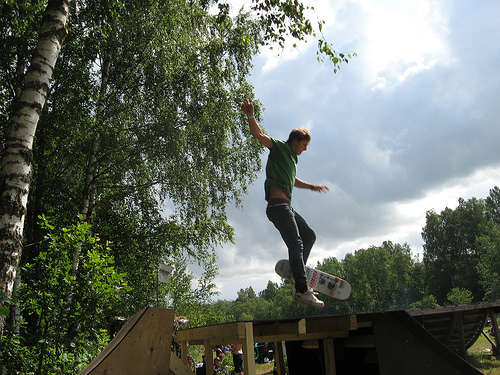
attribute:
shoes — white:
[289, 288, 328, 306]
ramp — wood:
[129, 290, 243, 353]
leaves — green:
[104, 137, 164, 221]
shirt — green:
[254, 134, 306, 191]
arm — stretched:
[224, 84, 275, 149]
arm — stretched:
[284, 168, 332, 203]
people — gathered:
[181, 312, 283, 369]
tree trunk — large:
[15, 3, 77, 326]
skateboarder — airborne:
[248, 93, 380, 320]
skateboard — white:
[266, 249, 366, 299]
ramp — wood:
[95, 280, 475, 370]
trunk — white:
[13, 11, 83, 198]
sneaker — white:
[274, 268, 341, 338]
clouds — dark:
[275, 23, 476, 201]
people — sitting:
[180, 324, 291, 373]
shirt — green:
[260, 131, 310, 202]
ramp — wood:
[81, 258, 471, 358]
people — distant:
[188, 317, 287, 373]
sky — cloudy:
[3, 8, 482, 260]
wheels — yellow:
[274, 258, 352, 303]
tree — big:
[4, 5, 79, 351]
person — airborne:
[250, 99, 355, 292]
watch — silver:
[244, 111, 257, 123]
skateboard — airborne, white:
[271, 252, 353, 303]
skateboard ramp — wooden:
[95, 301, 178, 372]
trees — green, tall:
[171, 189, 499, 324]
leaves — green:
[348, 250, 480, 297]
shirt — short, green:
[260, 126, 301, 197]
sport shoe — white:
[290, 282, 325, 310]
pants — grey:
[255, 195, 319, 295]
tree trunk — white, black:
[0, 58, 48, 341]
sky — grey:
[161, 0, 494, 298]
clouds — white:
[269, 38, 401, 238]